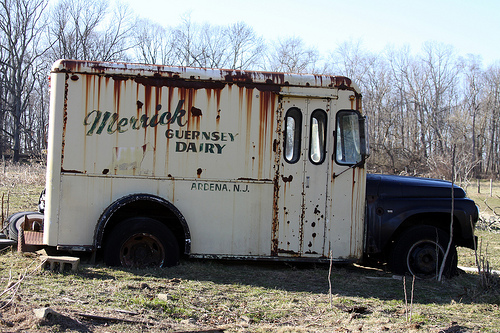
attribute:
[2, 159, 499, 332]
grass — green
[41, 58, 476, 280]
truck — white, old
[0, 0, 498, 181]
trees — bare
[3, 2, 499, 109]
sky — blue, bright, cloudy, white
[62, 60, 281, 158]
rust — brown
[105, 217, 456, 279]
tires — flat, black, rusty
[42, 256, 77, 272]
block — gray, cement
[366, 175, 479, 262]
front — black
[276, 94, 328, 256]
door — white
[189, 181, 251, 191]
ardenna, n.j. — green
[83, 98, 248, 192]
letters — blue, black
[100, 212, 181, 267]
tire — rear